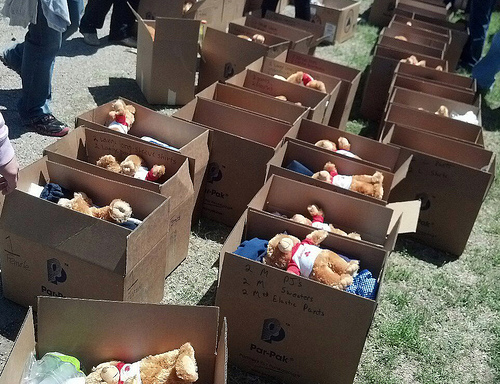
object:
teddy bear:
[260, 229, 361, 290]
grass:
[0, 0, 499, 383]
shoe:
[20, 112, 69, 136]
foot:
[19, 97, 71, 137]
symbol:
[47, 258, 69, 286]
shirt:
[285, 237, 322, 277]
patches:
[440, 322, 493, 382]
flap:
[386, 198, 422, 235]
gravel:
[10, 37, 16, 41]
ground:
[0, 0, 499, 383]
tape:
[167, 88, 178, 105]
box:
[127, 0, 202, 105]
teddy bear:
[310, 162, 383, 199]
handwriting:
[255, 280, 265, 287]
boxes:
[214, 207, 387, 383]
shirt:
[330, 170, 354, 189]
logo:
[260, 318, 285, 344]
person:
[0, 0, 84, 136]